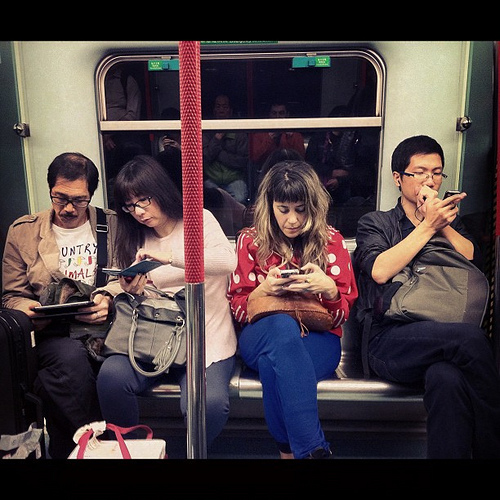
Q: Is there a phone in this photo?
A: Yes, there is a phone.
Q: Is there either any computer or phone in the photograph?
A: Yes, there is a phone.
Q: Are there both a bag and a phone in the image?
A: Yes, there are both a phone and a bag.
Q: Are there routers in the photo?
A: No, there are no routers.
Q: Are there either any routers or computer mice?
A: No, there are no routers or computer mice.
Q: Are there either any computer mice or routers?
A: No, there are no routers or computer mice.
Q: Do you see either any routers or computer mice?
A: No, there are no routers or computer mice.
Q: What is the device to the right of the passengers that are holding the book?
A: The device is a phone.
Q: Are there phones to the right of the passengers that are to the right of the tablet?
A: Yes, there is a phone to the right of the passengers.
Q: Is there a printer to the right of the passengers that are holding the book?
A: No, there is a phone to the right of the passengers.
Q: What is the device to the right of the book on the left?
A: The device is a phone.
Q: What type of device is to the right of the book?
A: The device is a phone.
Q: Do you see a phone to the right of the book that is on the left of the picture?
A: Yes, there is a phone to the right of the book.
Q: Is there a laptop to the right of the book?
A: No, there is a phone to the right of the book.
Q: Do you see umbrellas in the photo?
A: No, there are no umbrellas.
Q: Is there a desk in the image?
A: No, there are no desks.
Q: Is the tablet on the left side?
A: Yes, the tablet is on the left of the image.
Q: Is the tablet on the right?
A: No, the tablet is on the left of the image.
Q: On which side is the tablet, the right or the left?
A: The tablet is on the left of the image.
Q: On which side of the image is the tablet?
A: The tablet is on the left of the image.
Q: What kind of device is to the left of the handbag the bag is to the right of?
A: The device is a tablet.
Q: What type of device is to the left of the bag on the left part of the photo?
A: The device is a tablet.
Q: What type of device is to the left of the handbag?
A: The device is a tablet.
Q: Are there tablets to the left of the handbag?
A: Yes, there is a tablet to the left of the handbag.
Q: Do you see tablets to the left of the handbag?
A: Yes, there is a tablet to the left of the handbag.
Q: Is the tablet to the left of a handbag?
A: Yes, the tablet is to the left of a handbag.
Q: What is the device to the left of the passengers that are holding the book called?
A: The device is a tablet.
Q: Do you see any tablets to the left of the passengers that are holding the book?
A: Yes, there is a tablet to the left of the passengers.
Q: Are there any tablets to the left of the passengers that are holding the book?
A: Yes, there is a tablet to the left of the passengers.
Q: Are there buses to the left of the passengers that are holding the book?
A: No, there is a tablet to the left of the passengers.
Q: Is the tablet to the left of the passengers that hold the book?
A: Yes, the tablet is to the left of the passengers.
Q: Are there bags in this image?
A: Yes, there is a bag.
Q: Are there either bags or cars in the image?
A: Yes, there is a bag.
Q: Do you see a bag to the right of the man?
A: Yes, there is a bag to the right of the man.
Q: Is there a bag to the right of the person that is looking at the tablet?
A: Yes, there is a bag to the right of the man.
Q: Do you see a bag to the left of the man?
A: No, the bag is to the right of the man.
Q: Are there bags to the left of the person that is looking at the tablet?
A: No, the bag is to the right of the man.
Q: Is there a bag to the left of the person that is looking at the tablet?
A: No, the bag is to the right of the man.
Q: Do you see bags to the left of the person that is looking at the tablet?
A: No, the bag is to the right of the man.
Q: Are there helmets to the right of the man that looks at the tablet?
A: No, there is a bag to the right of the man.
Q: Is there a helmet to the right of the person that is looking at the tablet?
A: No, there is a bag to the right of the man.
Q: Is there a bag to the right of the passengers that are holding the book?
A: Yes, there is a bag to the right of the passengers.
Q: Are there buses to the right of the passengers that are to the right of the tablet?
A: No, there is a bag to the right of the passengers.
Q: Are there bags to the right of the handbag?
A: Yes, there is a bag to the right of the handbag.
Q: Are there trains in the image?
A: Yes, there is a train.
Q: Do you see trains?
A: Yes, there is a train.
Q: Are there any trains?
A: Yes, there is a train.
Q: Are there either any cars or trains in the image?
A: Yes, there is a train.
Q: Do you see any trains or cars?
A: Yes, there is a train.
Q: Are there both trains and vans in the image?
A: No, there is a train but no vans.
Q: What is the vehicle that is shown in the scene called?
A: The vehicle is a train.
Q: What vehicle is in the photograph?
A: The vehicle is a train.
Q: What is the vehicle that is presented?
A: The vehicle is a train.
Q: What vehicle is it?
A: The vehicle is a train.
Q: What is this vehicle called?
A: This is a train.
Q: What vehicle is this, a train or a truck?
A: This is a train.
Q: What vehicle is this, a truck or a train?
A: This is a train.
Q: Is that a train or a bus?
A: That is a train.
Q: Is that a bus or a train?
A: That is a train.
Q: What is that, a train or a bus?
A: That is a train.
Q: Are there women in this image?
A: Yes, there is a woman.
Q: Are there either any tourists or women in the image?
A: Yes, there is a woman.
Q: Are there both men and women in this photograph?
A: Yes, there are both a woman and a man.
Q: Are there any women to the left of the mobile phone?
A: Yes, there is a woman to the left of the mobile phone.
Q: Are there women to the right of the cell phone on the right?
A: No, the woman is to the left of the cell phone.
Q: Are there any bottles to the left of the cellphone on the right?
A: No, there is a woman to the left of the cell phone.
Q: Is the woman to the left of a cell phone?
A: Yes, the woman is to the left of a cell phone.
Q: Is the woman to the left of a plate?
A: No, the woman is to the left of a cell phone.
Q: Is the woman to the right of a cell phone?
A: No, the woman is to the left of a cell phone.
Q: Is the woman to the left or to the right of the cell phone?
A: The woman is to the left of the cell phone.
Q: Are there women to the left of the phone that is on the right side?
A: Yes, there is a woman to the left of the telephone.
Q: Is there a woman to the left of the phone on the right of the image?
A: Yes, there is a woman to the left of the telephone.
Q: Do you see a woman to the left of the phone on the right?
A: Yes, there is a woman to the left of the telephone.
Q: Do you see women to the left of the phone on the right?
A: Yes, there is a woman to the left of the telephone.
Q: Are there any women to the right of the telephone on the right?
A: No, the woman is to the left of the telephone.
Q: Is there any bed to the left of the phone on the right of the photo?
A: No, there is a woman to the left of the phone.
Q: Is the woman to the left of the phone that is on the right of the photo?
A: Yes, the woman is to the left of the telephone.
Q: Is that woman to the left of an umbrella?
A: No, the woman is to the left of the telephone.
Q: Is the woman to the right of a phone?
A: No, the woman is to the left of a phone.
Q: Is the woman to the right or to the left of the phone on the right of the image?
A: The woman is to the left of the phone.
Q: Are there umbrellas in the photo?
A: No, there are no umbrellas.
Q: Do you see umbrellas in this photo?
A: No, there are no umbrellas.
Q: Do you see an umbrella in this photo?
A: No, there are no umbrellas.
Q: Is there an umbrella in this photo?
A: No, there are no umbrellas.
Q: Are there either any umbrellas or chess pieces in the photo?
A: No, there are no umbrellas or chess pieces.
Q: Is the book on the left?
A: Yes, the book is on the left of the image.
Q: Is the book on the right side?
A: No, the book is on the left of the image.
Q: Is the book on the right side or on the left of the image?
A: The book is on the left of the image.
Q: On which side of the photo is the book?
A: The book is on the left of the image.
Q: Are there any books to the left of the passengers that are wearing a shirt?
A: Yes, there is a book to the left of the passengers.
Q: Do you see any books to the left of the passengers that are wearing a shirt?
A: Yes, there is a book to the left of the passengers.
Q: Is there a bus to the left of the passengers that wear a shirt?
A: No, there is a book to the left of the passengers.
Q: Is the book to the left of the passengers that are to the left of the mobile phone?
A: Yes, the book is to the left of the passengers.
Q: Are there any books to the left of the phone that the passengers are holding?
A: Yes, there is a book to the left of the telephone.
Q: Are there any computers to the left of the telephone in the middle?
A: No, there is a book to the left of the telephone.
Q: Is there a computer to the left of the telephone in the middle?
A: No, there is a book to the left of the telephone.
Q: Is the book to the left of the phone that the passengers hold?
A: Yes, the book is to the left of the phone.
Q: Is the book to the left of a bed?
A: No, the book is to the left of the phone.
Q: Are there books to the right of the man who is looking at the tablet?
A: Yes, there is a book to the right of the man.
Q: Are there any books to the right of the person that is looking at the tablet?
A: Yes, there is a book to the right of the man.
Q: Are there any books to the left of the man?
A: No, the book is to the right of the man.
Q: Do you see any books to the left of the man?
A: No, the book is to the right of the man.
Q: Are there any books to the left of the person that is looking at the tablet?
A: No, the book is to the right of the man.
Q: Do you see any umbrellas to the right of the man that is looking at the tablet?
A: No, there is a book to the right of the man.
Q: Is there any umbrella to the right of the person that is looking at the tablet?
A: No, there is a book to the right of the man.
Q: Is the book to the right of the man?
A: Yes, the book is to the right of the man.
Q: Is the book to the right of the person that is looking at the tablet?
A: Yes, the book is to the right of the man.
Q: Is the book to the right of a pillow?
A: No, the book is to the right of the man.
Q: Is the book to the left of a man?
A: No, the book is to the right of a man.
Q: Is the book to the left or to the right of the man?
A: The book is to the right of the man.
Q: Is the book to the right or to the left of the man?
A: The book is to the right of the man.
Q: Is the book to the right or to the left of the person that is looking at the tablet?
A: The book is to the right of the man.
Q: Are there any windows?
A: Yes, there is a window.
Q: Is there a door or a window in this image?
A: Yes, there is a window.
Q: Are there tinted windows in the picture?
A: Yes, there is a tinted window.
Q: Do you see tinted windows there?
A: Yes, there is a tinted window.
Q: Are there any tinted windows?
A: Yes, there is a tinted window.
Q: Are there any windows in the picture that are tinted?
A: Yes, there is a tinted window.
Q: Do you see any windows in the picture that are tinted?
A: Yes, there is a window that is tinted.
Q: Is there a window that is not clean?
A: Yes, there is a tinted window.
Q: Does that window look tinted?
A: Yes, the window is tinted.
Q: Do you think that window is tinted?
A: Yes, the window is tinted.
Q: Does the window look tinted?
A: Yes, the window is tinted.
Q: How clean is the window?
A: The window is tinted.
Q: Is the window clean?
A: No, the window is tinted.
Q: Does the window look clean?
A: No, the window is tinted.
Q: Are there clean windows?
A: No, there is a window but it is tinted.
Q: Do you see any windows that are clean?
A: No, there is a window but it is tinted.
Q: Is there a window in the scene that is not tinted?
A: No, there is a window but it is tinted.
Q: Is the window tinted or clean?
A: The window is tinted.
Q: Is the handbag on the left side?
A: Yes, the handbag is on the left of the image.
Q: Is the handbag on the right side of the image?
A: No, the handbag is on the left of the image.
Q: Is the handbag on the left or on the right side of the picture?
A: The handbag is on the left of the image.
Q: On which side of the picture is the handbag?
A: The handbag is on the left of the image.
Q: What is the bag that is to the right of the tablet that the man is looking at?
A: The bag is a handbag.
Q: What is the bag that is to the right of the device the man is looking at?
A: The bag is a handbag.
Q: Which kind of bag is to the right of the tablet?
A: The bag is a handbag.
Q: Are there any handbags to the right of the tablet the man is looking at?
A: Yes, there is a handbag to the right of the tablet.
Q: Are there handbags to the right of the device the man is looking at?
A: Yes, there is a handbag to the right of the tablet.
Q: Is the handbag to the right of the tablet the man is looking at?
A: Yes, the handbag is to the right of the tablet.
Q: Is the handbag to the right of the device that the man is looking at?
A: Yes, the handbag is to the right of the tablet.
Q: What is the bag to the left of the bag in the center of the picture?
A: The bag is a handbag.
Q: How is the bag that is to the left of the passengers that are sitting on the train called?
A: The bag is a handbag.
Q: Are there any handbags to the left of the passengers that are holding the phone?
A: Yes, there is a handbag to the left of the passengers.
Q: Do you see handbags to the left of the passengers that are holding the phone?
A: Yes, there is a handbag to the left of the passengers.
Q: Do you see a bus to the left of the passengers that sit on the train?
A: No, there is a handbag to the left of the passengers.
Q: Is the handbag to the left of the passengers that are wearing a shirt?
A: Yes, the handbag is to the left of the passengers.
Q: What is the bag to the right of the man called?
A: The bag is a handbag.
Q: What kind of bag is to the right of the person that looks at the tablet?
A: The bag is a handbag.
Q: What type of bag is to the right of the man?
A: The bag is a handbag.